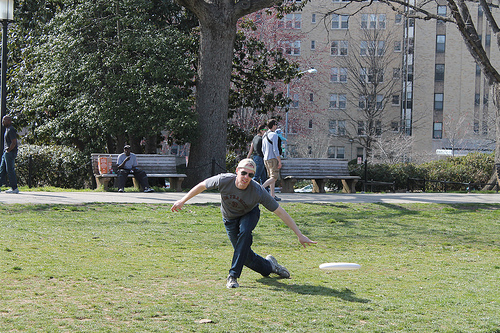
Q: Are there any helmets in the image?
A: No, there are no helmets.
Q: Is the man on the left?
A: Yes, the man is on the left of the image.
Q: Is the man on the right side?
A: No, the man is on the left of the image.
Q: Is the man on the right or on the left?
A: The man is on the left of the image.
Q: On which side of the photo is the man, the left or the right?
A: The man is on the left of the image.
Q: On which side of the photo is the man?
A: The man is on the left of the image.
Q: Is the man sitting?
A: Yes, the man is sitting.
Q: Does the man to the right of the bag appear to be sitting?
A: Yes, the man is sitting.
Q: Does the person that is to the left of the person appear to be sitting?
A: Yes, the man is sitting.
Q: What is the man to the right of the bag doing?
A: The man is sitting.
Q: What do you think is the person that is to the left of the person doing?
A: The man is sitting.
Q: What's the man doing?
A: The man is sitting.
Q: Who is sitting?
A: The man is sitting.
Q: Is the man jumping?
A: No, the man is sitting.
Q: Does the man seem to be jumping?
A: No, the man is sitting.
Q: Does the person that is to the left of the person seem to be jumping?
A: No, the man is sitting.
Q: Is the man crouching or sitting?
A: The man is sitting.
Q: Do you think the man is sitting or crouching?
A: The man is sitting.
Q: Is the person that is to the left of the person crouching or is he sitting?
A: The man is sitting.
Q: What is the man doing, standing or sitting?
A: The man is sitting.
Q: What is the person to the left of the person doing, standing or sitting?
A: The man is sitting.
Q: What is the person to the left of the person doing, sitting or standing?
A: The man is sitting.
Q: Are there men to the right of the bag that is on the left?
A: Yes, there is a man to the right of the bag.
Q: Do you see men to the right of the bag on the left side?
A: Yes, there is a man to the right of the bag.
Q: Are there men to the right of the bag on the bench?
A: Yes, there is a man to the right of the bag.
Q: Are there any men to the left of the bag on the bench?
A: No, the man is to the right of the bag.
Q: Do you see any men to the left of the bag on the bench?
A: No, the man is to the right of the bag.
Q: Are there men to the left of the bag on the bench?
A: No, the man is to the right of the bag.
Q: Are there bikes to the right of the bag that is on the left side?
A: No, there is a man to the right of the bag.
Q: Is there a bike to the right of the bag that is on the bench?
A: No, there is a man to the right of the bag.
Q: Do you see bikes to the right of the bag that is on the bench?
A: No, there is a man to the right of the bag.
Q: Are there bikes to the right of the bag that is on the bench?
A: No, there is a man to the right of the bag.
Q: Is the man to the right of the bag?
A: Yes, the man is to the right of the bag.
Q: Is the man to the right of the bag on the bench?
A: Yes, the man is to the right of the bag.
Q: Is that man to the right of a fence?
A: No, the man is to the right of the bag.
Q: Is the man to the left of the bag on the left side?
A: No, the man is to the right of the bag.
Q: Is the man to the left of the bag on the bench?
A: No, the man is to the right of the bag.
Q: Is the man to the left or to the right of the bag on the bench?
A: The man is to the right of the bag.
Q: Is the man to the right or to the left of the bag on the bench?
A: The man is to the right of the bag.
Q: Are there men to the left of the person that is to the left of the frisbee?
A: Yes, there is a man to the left of the person.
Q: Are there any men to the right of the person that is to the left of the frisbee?
A: No, the man is to the left of the person.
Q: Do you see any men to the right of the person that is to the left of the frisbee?
A: No, the man is to the left of the person.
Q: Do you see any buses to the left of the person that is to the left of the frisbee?
A: No, there is a man to the left of the person.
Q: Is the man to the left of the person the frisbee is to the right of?
A: Yes, the man is to the left of the person.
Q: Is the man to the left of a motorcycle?
A: No, the man is to the left of the person.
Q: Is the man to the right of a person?
A: No, the man is to the left of a person.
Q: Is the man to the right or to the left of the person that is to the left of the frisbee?
A: The man is to the left of the person.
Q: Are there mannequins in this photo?
A: No, there are no mannequins.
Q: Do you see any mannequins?
A: No, there are no mannequins.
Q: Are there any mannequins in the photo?
A: No, there are no mannequins.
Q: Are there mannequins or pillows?
A: No, there are no mannequins or pillows.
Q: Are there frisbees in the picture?
A: Yes, there is a frisbee.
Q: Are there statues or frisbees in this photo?
A: Yes, there is a frisbee.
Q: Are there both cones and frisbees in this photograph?
A: No, there is a frisbee but no cones.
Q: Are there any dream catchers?
A: No, there are no dream catchers.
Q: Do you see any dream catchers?
A: No, there are no dream catchers.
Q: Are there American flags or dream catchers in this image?
A: No, there are no dream catchers or American flags.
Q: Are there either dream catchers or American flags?
A: No, there are no dream catchers or American flags.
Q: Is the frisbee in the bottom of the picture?
A: Yes, the frisbee is in the bottom of the image.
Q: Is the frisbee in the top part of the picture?
A: No, the frisbee is in the bottom of the image.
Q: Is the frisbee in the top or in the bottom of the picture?
A: The frisbee is in the bottom of the image.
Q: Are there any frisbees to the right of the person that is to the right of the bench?
A: Yes, there is a frisbee to the right of the person.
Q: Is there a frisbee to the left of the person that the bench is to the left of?
A: No, the frisbee is to the right of the person.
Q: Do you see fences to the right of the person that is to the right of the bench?
A: No, there is a frisbee to the right of the person.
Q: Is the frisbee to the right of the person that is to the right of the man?
A: Yes, the frisbee is to the right of the person.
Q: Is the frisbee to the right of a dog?
A: No, the frisbee is to the right of the person.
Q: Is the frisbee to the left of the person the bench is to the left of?
A: No, the frisbee is to the right of the person.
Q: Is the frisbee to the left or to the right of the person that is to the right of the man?
A: The frisbee is to the right of the person.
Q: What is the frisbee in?
A: The frisbee is in the air.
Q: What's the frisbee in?
A: The frisbee is in the air.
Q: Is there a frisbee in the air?
A: Yes, there is a frisbee in the air.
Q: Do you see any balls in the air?
A: No, there is a frisbee in the air.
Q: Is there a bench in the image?
A: Yes, there is a bench.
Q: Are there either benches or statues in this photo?
A: Yes, there is a bench.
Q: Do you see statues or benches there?
A: Yes, there is a bench.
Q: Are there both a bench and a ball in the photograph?
A: No, there is a bench but no balls.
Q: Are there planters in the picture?
A: No, there are no planters.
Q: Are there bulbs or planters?
A: No, there are no planters or bulbs.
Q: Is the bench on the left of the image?
A: Yes, the bench is on the left of the image.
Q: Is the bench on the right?
A: No, the bench is on the left of the image.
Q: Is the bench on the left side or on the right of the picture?
A: The bench is on the left of the image.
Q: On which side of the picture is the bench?
A: The bench is on the left of the image.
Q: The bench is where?
A: The bench is on the road.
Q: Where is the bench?
A: The bench is on the road.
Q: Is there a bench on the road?
A: Yes, there is a bench on the road.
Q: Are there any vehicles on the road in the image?
A: No, there is a bench on the road.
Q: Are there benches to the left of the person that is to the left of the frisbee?
A: Yes, there is a bench to the left of the person.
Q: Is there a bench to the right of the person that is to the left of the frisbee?
A: No, the bench is to the left of the person.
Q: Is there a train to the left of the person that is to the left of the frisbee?
A: No, there is a bench to the left of the person.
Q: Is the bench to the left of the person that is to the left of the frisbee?
A: Yes, the bench is to the left of the person.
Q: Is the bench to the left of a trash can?
A: No, the bench is to the left of the person.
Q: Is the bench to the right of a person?
A: No, the bench is to the left of a person.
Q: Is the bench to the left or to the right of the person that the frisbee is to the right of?
A: The bench is to the left of the person.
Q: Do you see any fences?
A: No, there are no fences.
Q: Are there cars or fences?
A: No, there are no cars or fences.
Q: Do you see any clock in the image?
A: No, there are no clocks.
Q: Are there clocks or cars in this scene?
A: No, there are no clocks or cars.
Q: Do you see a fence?
A: No, there are no fences.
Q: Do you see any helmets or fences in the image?
A: No, there are no fences or helmets.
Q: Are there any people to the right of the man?
A: Yes, there is a person to the right of the man.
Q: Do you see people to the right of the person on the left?
A: Yes, there is a person to the right of the man.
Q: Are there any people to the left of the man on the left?
A: No, the person is to the right of the man.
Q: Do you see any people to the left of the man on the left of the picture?
A: No, the person is to the right of the man.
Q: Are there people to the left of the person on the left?
A: No, the person is to the right of the man.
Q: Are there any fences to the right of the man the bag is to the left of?
A: No, there is a person to the right of the man.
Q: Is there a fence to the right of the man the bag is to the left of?
A: No, there is a person to the right of the man.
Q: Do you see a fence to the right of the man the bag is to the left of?
A: No, there is a person to the right of the man.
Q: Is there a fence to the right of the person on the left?
A: No, there is a person to the right of the man.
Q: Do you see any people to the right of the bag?
A: Yes, there is a person to the right of the bag.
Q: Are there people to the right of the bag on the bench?
A: Yes, there is a person to the right of the bag.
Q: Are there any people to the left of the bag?
A: No, the person is to the right of the bag.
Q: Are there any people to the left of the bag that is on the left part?
A: No, the person is to the right of the bag.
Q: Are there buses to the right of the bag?
A: No, there is a person to the right of the bag.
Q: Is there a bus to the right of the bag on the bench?
A: No, there is a person to the right of the bag.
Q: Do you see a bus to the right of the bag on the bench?
A: No, there is a person to the right of the bag.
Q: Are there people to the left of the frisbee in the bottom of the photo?
A: Yes, there is a person to the left of the frisbee.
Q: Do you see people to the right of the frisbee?
A: No, the person is to the left of the frisbee.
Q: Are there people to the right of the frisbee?
A: No, the person is to the left of the frisbee.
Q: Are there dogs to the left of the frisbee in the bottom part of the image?
A: No, there is a person to the left of the frisbee.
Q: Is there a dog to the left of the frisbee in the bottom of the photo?
A: No, there is a person to the left of the frisbee.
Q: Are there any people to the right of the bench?
A: Yes, there is a person to the right of the bench.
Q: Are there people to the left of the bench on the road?
A: No, the person is to the right of the bench.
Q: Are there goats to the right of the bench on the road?
A: No, there is a person to the right of the bench.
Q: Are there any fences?
A: No, there are no fences.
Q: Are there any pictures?
A: No, there are no pictures.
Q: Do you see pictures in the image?
A: No, there are no pictures.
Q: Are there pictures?
A: No, there are no pictures.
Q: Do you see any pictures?
A: No, there are no pictures.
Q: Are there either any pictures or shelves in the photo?
A: No, there are no pictures or shelves.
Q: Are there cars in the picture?
A: No, there are no cars.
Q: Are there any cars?
A: No, there are no cars.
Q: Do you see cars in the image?
A: No, there are no cars.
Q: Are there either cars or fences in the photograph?
A: No, there are no cars or fences.